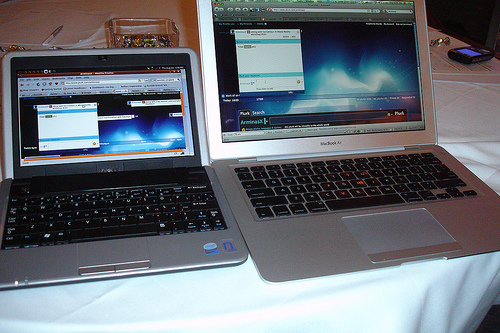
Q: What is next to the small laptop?
A: A bigger laptop.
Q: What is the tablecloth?
A: White.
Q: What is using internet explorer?
A: The laptop.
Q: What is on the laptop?
A: The black keyboard.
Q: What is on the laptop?
A: Black keyboard.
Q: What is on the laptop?
A: Black keyboard.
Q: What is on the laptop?
A: Black keyboard.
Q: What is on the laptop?
A: Black keyboard.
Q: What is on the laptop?
A: Black keyboard.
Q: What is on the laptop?
A: Black keyboard.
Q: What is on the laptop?
A: Black keyboard.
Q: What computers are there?
A: Laptops.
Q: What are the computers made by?
A: Apple.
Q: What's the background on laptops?
A: Blue lasers.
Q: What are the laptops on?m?
A: Table.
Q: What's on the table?
A: Tablecloth.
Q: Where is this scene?
A: Room.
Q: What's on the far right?
A: Cell phones.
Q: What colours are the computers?
A: Silver.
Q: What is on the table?
A: Laptops.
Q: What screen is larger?
A: The right one.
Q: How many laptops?
A: Two.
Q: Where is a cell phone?
A: To the right.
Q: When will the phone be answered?
A: If it rings.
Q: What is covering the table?
A: A tablecloth.